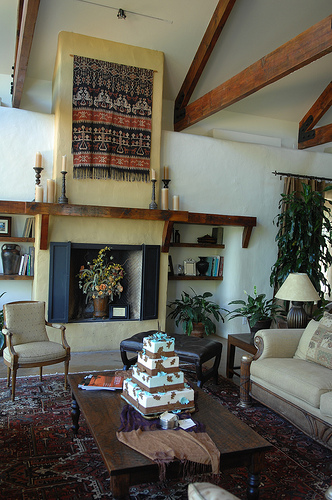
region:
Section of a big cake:
[141, 324, 179, 353]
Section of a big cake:
[131, 351, 192, 372]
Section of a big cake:
[120, 382, 218, 418]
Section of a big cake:
[140, 335, 191, 354]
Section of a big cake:
[134, 348, 199, 379]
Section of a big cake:
[127, 358, 185, 392]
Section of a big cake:
[117, 375, 199, 424]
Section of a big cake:
[140, 332, 179, 356]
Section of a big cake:
[124, 347, 195, 382]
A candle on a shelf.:
[151, 169, 157, 208]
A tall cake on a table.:
[121, 330, 194, 418]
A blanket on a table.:
[116, 398, 220, 484]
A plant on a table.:
[166, 286, 230, 338]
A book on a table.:
[78, 371, 123, 390]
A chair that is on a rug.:
[3, 300, 70, 395]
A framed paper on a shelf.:
[107, 304, 128, 318]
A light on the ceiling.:
[115, 8, 126, 19]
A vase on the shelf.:
[196, 256, 208, 275]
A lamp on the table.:
[275, 274, 319, 329]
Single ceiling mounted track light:
[68, 0, 174, 28]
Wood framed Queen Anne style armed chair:
[2, 300, 69, 398]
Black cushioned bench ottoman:
[119, 330, 223, 386]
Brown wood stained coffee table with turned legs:
[68, 371, 276, 499]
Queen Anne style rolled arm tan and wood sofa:
[237, 314, 330, 448]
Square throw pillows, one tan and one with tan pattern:
[297, 316, 331, 368]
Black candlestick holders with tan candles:
[29, 153, 180, 210]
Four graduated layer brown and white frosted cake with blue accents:
[121, 331, 194, 416]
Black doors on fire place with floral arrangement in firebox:
[49, 240, 160, 320]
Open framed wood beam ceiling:
[174, 3, 330, 131]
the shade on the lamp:
[274, 272, 321, 301]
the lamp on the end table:
[273, 273, 320, 328]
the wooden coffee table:
[66, 373, 273, 498]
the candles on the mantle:
[32, 152, 178, 210]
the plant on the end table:
[224, 285, 287, 335]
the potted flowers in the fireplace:
[76, 245, 130, 318]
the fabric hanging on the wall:
[69, 53, 157, 180]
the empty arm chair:
[2, 300, 71, 402]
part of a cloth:
[167, 452, 190, 483]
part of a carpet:
[59, 448, 73, 465]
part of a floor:
[54, 451, 80, 478]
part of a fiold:
[169, 446, 185, 466]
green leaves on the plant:
[253, 292, 270, 316]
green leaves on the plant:
[253, 292, 272, 320]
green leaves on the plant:
[205, 303, 225, 331]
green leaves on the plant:
[182, 301, 213, 331]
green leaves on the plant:
[188, 290, 227, 320]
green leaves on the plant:
[269, 247, 291, 276]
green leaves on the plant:
[302, 264, 328, 289]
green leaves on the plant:
[292, 217, 305, 246]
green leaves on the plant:
[313, 209, 326, 247]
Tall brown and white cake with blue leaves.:
[122, 332, 195, 416]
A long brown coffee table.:
[65, 373, 275, 499]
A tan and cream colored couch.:
[239, 309, 331, 451]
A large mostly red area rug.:
[1, 371, 331, 499]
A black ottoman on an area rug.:
[120, 329, 222, 389]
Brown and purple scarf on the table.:
[116, 404, 221, 486]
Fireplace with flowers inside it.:
[46, 241, 162, 324]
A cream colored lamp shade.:
[274, 272, 320, 302]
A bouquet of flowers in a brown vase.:
[77, 245, 126, 319]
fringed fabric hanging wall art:
[67, 53, 158, 183]